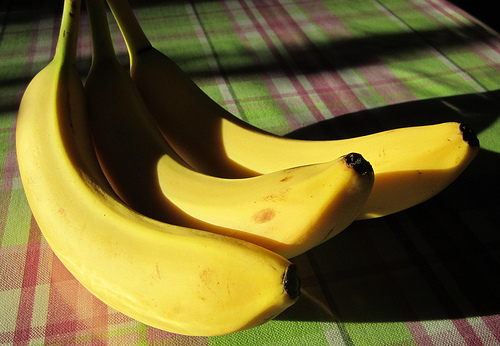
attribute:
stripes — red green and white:
[154, 2, 498, 130]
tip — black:
[340, 147, 372, 185]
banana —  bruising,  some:
[10, 10, 499, 326]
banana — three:
[104, 0, 481, 218]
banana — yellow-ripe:
[14, 0, 302, 337]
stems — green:
[48, 1, 162, 76]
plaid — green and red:
[0, 0, 499, 343]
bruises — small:
[183, 180, 289, 304]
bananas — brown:
[1, 67, 409, 247]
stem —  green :
[43, 2, 154, 57]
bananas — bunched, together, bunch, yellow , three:
[10, 1, 488, 343]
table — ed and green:
[7, 6, 496, 336]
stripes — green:
[212, 312, 352, 346]